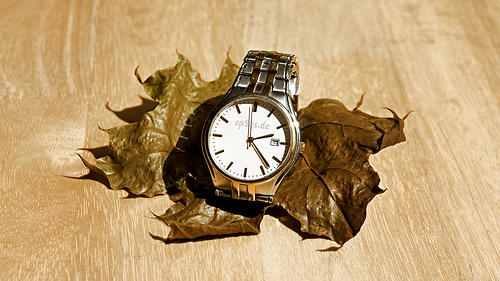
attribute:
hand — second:
[246, 138, 273, 174]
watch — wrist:
[189, 45, 314, 215]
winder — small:
[298, 138, 306, 153]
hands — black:
[247, 135, 274, 169]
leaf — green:
[91, 55, 240, 192]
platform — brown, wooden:
[5, 5, 96, 280]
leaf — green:
[305, 113, 400, 241]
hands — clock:
[242, 128, 274, 172]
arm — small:
[244, 107, 252, 137]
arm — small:
[252, 134, 273, 141]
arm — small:
[250, 143, 270, 170]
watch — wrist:
[203, 93, 307, 202]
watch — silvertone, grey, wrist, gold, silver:
[198, 49, 307, 205]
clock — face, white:
[188, 83, 333, 190]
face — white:
[209, 100, 292, 181]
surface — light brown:
[2, 130, 94, 266]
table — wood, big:
[3, 3, 496, 278]